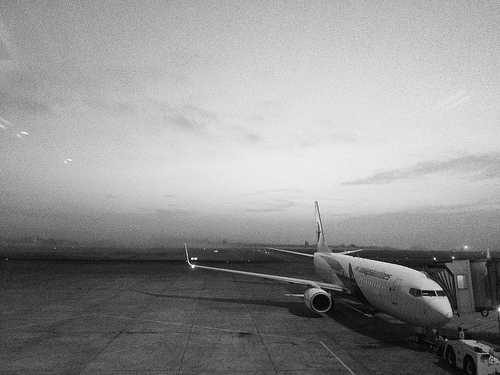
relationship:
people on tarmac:
[388, 306, 488, 367] [77, 280, 322, 372]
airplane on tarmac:
[184, 200, 455, 352] [163, 319, 287, 358]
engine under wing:
[284, 287, 333, 314] [169, 236, 349, 306]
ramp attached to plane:
[434, 254, 495, 320] [218, 202, 435, 336]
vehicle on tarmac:
[437, 328, 497, 371] [287, 319, 340, 366]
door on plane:
[389, 277, 402, 304] [209, 226, 425, 347]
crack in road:
[164, 311, 228, 341] [151, 319, 279, 341]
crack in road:
[157, 299, 271, 332] [123, 286, 224, 334]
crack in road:
[188, 329, 258, 351] [116, 285, 207, 331]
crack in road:
[49, 331, 322, 335] [224, 307, 276, 347]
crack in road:
[184, 337, 230, 347] [180, 335, 258, 358]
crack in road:
[146, 293, 203, 334] [150, 290, 192, 308]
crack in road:
[49, 331, 322, 335] [180, 328, 253, 348]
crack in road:
[205, 300, 283, 350] [205, 323, 296, 352]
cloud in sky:
[0, 60, 499, 213] [329, 113, 441, 205]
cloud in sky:
[313, 150, 405, 193] [172, 152, 253, 202]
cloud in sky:
[0, 60, 499, 213] [292, 138, 415, 198]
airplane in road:
[184, 200, 455, 352] [0, 264, 500, 362]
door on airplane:
[378, 274, 415, 307] [227, 212, 481, 345]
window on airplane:
[409, 275, 442, 306] [245, 202, 447, 330]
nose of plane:
[439, 303, 460, 329] [172, 192, 499, 362]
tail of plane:
[302, 193, 325, 262] [172, 192, 499, 362]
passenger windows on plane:
[349, 261, 398, 288] [184, 193, 455, 341]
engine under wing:
[298, 287, 336, 317] [181, 240, 347, 298]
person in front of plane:
[453, 322, 463, 338] [184, 193, 455, 341]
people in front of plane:
[428, 325, 449, 345] [184, 193, 455, 341]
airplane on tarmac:
[178, 192, 468, 349] [2, 254, 462, 373]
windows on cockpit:
[408, 286, 449, 301] [406, 273, 452, 322]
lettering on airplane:
[354, 262, 398, 280] [171, 191, 456, 333]